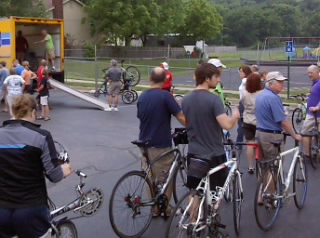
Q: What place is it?
A: It is a parking lot.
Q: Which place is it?
A: It is a parking lot.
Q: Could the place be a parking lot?
A: Yes, it is a parking lot.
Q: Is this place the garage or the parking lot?
A: It is the parking lot.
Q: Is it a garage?
A: No, it is a parking lot.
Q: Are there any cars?
A: No, there are no cars.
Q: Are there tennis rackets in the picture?
A: No, there are no tennis rackets.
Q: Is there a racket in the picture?
A: No, there are no rackets.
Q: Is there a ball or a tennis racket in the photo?
A: No, there are no rackets or balls.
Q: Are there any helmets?
A: No, there are no helmets.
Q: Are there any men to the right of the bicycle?
A: Yes, there is a man to the right of the bicycle.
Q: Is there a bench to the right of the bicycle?
A: No, there is a man to the right of the bicycle.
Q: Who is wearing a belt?
A: The man is wearing a belt.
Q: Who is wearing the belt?
A: The man is wearing a belt.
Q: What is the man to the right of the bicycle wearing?
A: The man is wearing a belt.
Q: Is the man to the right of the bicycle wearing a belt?
A: Yes, the man is wearing a belt.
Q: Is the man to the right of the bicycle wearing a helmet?
A: No, the man is wearing a belt.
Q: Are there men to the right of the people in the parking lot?
A: Yes, there is a man to the right of the people.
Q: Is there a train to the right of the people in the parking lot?
A: No, there is a man to the right of the people.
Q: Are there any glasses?
A: No, there are no glasses.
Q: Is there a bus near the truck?
A: No, there is a man near the truck.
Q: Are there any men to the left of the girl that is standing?
A: Yes, there is a man to the left of the girl.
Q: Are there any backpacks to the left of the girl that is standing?
A: No, there is a man to the left of the girl.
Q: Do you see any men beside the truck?
A: Yes, there is a man beside the truck.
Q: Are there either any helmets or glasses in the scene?
A: No, there are no glasses or helmets.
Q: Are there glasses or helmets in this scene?
A: No, there are no glasses or helmets.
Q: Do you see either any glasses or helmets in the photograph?
A: No, there are no glasses or helmets.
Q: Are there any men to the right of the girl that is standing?
A: Yes, there is a man to the right of the girl.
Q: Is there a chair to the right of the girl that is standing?
A: No, there is a man to the right of the girl.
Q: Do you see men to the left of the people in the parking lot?
A: Yes, there is a man to the left of the people.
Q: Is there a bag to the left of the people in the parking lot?
A: No, there is a man to the left of the people.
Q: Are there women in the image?
A: Yes, there is a woman.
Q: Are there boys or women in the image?
A: Yes, there is a woman.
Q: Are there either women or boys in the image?
A: Yes, there is a woman.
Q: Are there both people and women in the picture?
A: Yes, there are both a woman and a person.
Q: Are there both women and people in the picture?
A: Yes, there are both a woman and a person.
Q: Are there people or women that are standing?
A: Yes, the woman is standing.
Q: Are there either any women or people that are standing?
A: Yes, the woman is standing.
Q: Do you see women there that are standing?
A: Yes, there is a woman that is standing.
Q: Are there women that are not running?
A: Yes, there is a woman that is standing.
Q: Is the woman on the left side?
A: Yes, the woman is on the left of the image.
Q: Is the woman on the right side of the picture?
A: No, the woman is on the left of the image.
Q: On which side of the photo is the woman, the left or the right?
A: The woman is on the left of the image.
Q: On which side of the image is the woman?
A: The woman is on the left of the image.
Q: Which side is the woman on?
A: The woman is on the left of the image.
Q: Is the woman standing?
A: Yes, the woman is standing.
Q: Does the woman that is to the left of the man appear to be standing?
A: Yes, the woman is standing.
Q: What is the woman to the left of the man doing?
A: The woman is standing.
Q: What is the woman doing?
A: The woman is standing.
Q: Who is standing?
A: The woman is standing.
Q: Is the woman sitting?
A: No, the woman is standing.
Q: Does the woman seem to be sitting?
A: No, the woman is standing.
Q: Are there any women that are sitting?
A: No, there is a woman but she is standing.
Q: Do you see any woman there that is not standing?
A: No, there is a woman but she is standing.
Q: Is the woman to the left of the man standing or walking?
A: The woman is standing.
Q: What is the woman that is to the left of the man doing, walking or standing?
A: The woman is standing.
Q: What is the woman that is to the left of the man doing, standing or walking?
A: The woman is standing.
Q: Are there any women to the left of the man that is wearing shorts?
A: Yes, there is a woman to the left of the man.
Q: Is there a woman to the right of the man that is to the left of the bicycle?
A: No, the woman is to the left of the man.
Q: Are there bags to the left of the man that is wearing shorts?
A: No, there is a woman to the left of the man.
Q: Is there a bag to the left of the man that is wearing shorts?
A: No, there is a woman to the left of the man.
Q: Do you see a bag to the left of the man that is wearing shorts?
A: No, there is a woman to the left of the man.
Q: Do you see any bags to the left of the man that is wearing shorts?
A: No, there is a woman to the left of the man.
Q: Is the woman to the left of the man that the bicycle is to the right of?
A: Yes, the woman is to the left of the man.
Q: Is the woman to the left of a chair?
A: No, the woman is to the left of the man.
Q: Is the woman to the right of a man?
A: No, the woman is to the left of a man.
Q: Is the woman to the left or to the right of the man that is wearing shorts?
A: The woman is to the left of the man.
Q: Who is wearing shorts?
A: The woman is wearing shorts.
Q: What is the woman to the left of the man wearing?
A: The woman is wearing shorts.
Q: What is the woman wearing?
A: The woman is wearing shorts.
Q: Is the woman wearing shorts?
A: Yes, the woman is wearing shorts.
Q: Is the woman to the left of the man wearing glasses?
A: No, the woman is wearing shorts.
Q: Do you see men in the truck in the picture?
A: Yes, there is a man in the truck.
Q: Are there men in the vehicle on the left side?
A: Yes, there is a man in the truck.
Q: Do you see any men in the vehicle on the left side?
A: Yes, there is a man in the truck.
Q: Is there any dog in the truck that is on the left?
A: No, there is a man in the truck.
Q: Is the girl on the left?
A: Yes, the girl is on the left of the image.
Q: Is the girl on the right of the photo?
A: No, the girl is on the left of the image.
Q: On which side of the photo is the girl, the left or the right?
A: The girl is on the left of the image.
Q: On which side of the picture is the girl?
A: The girl is on the left of the image.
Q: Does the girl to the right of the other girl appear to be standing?
A: Yes, the girl is standing.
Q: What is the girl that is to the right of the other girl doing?
A: The girl is standing.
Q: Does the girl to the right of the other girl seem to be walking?
A: No, the girl is standing.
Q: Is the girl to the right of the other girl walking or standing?
A: The girl is standing.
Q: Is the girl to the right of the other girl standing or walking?
A: The girl is standing.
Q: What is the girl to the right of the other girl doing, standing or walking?
A: The girl is standing.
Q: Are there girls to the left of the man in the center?
A: Yes, there is a girl to the left of the man.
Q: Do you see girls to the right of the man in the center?
A: No, the girl is to the left of the man.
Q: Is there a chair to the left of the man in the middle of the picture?
A: No, there is a girl to the left of the man.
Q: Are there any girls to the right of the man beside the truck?
A: Yes, there is a girl to the right of the man.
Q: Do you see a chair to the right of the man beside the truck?
A: No, there is a girl to the right of the man.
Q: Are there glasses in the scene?
A: No, there are no glasses.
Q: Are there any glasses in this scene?
A: No, there are no glasses.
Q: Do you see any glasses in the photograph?
A: No, there are no glasses.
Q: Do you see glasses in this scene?
A: No, there are no glasses.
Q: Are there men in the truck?
A: Yes, there is a man in the truck.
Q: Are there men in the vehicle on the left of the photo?
A: Yes, there is a man in the truck.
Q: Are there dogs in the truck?
A: No, there is a man in the truck.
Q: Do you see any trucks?
A: Yes, there is a truck.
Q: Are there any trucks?
A: Yes, there is a truck.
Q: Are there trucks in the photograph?
A: Yes, there is a truck.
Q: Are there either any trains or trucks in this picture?
A: Yes, there is a truck.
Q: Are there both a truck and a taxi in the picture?
A: No, there is a truck but no taxis.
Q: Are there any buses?
A: No, there are no buses.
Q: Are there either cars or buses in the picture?
A: No, there are no buses or cars.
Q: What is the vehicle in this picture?
A: The vehicle is a truck.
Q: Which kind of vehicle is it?
A: The vehicle is a truck.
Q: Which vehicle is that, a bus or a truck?
A: That is a truck.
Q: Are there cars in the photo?
A: No, there are no cars.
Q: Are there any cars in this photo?
A: No, there are no cars.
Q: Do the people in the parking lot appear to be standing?
A: Yes, the people are standing.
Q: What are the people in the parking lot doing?
A: The people are standing.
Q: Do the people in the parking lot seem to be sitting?
A: No, the people are standing.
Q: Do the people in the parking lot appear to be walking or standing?
A: The people are standing.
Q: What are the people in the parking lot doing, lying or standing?
A: The people are standing.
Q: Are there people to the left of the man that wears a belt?
A: Yes, there are people to the left of the man.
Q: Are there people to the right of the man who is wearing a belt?
A: No, the people are to the left of the man.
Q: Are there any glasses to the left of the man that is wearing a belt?
A: No, there are people to the left of the man.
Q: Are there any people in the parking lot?
A: Yes, there are people in the parking lot.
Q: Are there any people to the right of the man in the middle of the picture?
A: Yes, there are people to the right of the man.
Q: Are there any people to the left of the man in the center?
A: No, the people are to the right of the man.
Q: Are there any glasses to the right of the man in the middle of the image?
A: No, there are people to the right of the man.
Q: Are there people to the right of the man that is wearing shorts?
A: Yes, there are people to the right of the man.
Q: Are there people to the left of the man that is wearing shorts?
A: No, the people are to the right of the man.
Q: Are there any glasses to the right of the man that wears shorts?
A: No, there are people to the right of the man.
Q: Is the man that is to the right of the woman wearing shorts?
A: Yes, the man is wearing shorts.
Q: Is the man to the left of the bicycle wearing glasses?
A: No, the man is wearing shorts.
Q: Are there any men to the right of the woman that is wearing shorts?
A: Yes, there is a man to the right of the woman.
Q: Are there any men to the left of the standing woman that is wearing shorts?
A: No, the man is to the right of the woman.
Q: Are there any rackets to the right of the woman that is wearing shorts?
A: No, there is a man to the right of the woman.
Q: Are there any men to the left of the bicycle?
A: Yes, there is a man to the left of the bicycle.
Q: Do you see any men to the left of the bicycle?
A: Yes, there is a man to the left of the bicycle.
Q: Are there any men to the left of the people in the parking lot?
A: Yes, there is a man to the left of the people.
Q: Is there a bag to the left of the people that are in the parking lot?
A: No, there is a man to the left of the people.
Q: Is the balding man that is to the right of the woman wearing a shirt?
A: Yes, the man is wearing a shirt.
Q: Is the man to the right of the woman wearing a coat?
A: No, the man is wearing a shirt.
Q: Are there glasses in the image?
A: No, there are no glasses.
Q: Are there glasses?
A: No, there are no glasses.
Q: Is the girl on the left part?
A: Yes, the girl is on the left of the image.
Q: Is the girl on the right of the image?
A: No, the girl is on the left of the image.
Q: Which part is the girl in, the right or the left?
A: The girl is on the left of the image.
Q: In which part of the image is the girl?
A: The girl is on the left of the image.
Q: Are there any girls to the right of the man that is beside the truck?
A: Yes, there is a girl to the right of the man.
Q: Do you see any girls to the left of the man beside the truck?
A: No, the girl is to the right of the man.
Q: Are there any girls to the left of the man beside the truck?
A: No, the girl is to the right of the man.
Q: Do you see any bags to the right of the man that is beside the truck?
A: No, there is a girl to the right of the man.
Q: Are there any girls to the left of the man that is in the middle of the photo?
A: Yes, there is a girl to the left of the man.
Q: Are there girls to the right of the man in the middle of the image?
A: No, the girl is to the left of the man.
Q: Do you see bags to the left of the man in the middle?
A: No, there is a girl to the left of the man.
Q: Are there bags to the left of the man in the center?
A: No, there is a girl to the left of the man.